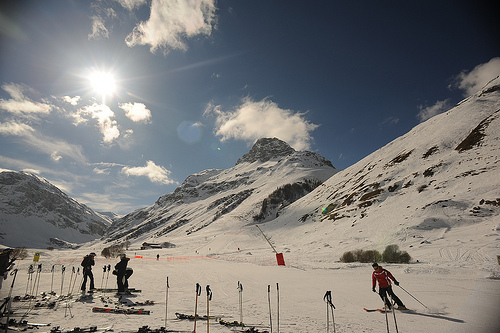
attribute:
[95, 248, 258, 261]
boundaries — orange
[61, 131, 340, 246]
mountain — steep, snow-covered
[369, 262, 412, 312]
person — standing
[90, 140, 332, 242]
snow mountain — snow-covered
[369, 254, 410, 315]
person — skiing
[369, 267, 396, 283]
coat — red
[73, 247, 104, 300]
people — skiing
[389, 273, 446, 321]
ski poles — stuck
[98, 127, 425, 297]
mountaintops — snow covered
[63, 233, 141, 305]
man walking — standing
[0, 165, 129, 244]
mountain — white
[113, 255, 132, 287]
people — three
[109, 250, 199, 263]
fence — orange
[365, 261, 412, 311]
skier — red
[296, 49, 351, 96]
ground — white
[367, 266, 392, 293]
jacket — red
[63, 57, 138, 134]
sun — bright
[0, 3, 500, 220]
sky — blue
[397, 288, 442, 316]
poles — standing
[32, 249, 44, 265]
sign — yellow